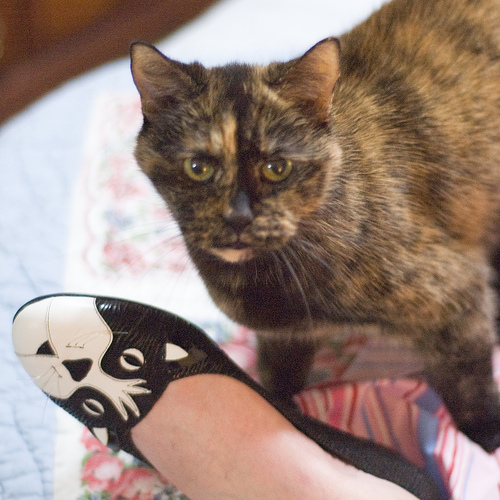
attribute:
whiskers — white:
[264, 232, 369, 337]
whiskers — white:
[143, 229, 204, 281]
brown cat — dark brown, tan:
[128, 0, 498, 453]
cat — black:
[121, 2, 499, 397]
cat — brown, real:
[117, 2, 498, 466]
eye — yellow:
[260, 159, 295, 183]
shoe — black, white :
[10, 294, 444, 496]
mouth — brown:
[203, 218, 251, 258]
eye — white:
[107, 342, 148, 365]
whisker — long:
[282, 244, 322, 307]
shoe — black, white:
[10, 292, 193, 452]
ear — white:
[155, 335, 196, 367]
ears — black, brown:
[128, 40, 341, 122]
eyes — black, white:
[170, 145, 298, 190]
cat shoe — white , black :
[9, 285, 446, 498]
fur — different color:
[237, 100, 330, 200]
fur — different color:
[181, 100, 235, 182]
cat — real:
[132, 1, 499, 431]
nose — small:
[220, 192, 256, 233]